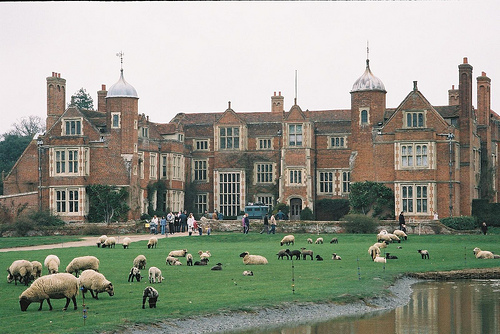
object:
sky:
[0, 0, 500, 141]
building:
[0, 41, 499, 223]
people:
[149, 210, 289, 240]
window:
[219, 126, 239, 149]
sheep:
[6, 254, 113, 311]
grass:
[0, 232, 500, 334]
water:
[432, 292, 465, 307]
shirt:
[187, 218, 196, 232]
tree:
[347, 179, 395, 219]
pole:
[0, 204, 67, 226]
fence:
[0, 221, 137, 237]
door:
[290, 197, 303, 222]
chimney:
[271, 91, 284, 112]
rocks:
[125, 275, 423, 334]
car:
[245, 206, 268, 220]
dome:
[105, 80, 140, 98]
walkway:
[0, 230, 213, 251]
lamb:
[239, 251, 268, 265]